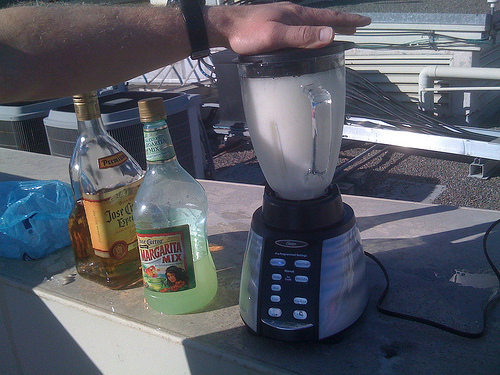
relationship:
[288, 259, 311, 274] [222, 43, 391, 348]
button on blender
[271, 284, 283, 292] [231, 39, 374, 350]
button on blender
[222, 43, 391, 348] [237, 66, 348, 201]
blender with beverages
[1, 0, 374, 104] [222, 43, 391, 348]
arm reaches blender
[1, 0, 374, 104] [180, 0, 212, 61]
arm with band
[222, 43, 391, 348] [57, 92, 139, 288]
blender with beverage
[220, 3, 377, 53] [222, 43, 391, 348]
hand on blender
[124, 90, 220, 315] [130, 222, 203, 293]
bottle with label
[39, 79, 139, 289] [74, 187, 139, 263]
bottle with label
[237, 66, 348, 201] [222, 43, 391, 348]
beverages in blender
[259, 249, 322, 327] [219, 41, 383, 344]
buttons on blenders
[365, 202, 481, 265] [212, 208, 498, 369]
shadows on surface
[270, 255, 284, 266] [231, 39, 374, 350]
button on blender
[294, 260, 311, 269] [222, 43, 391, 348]
button on blender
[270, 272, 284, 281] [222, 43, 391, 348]
button on blender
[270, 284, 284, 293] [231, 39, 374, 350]
button on blender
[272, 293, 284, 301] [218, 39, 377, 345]
button on blender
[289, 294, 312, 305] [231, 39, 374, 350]
button on blender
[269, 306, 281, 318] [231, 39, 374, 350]
button on blender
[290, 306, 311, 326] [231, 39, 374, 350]
button on blender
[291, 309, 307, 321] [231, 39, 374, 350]
button on blender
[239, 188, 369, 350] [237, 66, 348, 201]
blender with beverages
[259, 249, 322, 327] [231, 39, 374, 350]
buttons on blender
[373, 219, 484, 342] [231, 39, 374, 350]
cord on blender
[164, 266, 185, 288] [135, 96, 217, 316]
woman on bottle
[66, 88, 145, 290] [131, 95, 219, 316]
bottle next to bottle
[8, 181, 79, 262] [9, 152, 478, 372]
bag on table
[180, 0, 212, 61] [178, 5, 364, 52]
band on hand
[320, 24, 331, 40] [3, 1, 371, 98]
fingernail of man